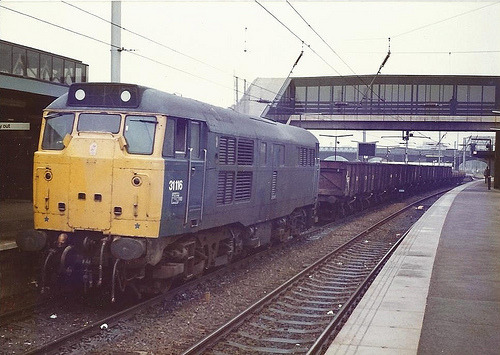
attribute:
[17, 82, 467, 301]
train — yellow, gray, black